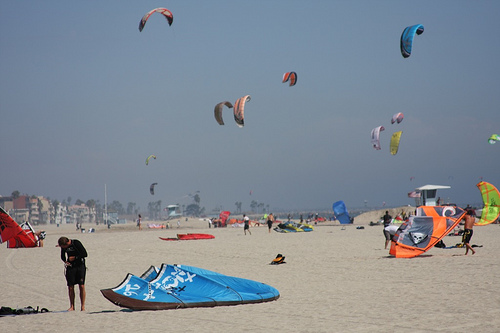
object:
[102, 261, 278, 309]
parachute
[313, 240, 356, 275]
sand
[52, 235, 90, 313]
man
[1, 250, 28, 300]
ground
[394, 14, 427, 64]
kite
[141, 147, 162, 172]
kite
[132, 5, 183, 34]
kite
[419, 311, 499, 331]
beach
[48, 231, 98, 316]
person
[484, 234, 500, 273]
ground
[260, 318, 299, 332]
beach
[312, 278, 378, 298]
ground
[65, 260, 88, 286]
shorts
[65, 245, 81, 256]
zebra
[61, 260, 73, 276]
something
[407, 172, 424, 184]
kites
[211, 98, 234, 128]
kite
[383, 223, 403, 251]
man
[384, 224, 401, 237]
shirt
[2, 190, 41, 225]
buildings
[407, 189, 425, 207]
flag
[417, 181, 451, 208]
lifeguard tower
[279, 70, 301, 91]
kite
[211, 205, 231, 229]
objects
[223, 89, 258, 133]
paraglider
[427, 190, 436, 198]
window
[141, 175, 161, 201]
kite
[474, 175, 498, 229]
parachute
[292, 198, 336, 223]
distance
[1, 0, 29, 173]
sky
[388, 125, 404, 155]
kite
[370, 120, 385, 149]
kite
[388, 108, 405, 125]
kite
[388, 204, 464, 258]
kite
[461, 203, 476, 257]
man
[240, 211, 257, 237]
outfit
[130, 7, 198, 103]
sky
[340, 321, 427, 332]
beach